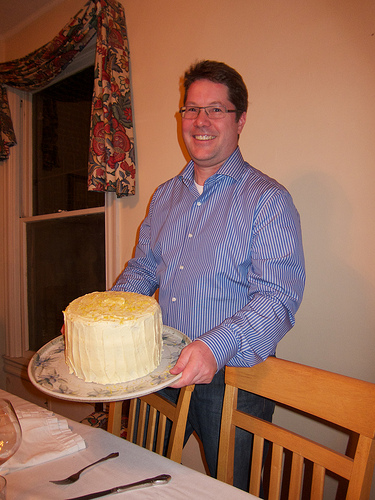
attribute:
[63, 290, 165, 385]
cake — frosted, tall, homemade, cream colored, round, multi-layer, for celebration, yellow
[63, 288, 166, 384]
frosting — white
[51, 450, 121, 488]
fork — silver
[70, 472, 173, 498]
butter knife — silver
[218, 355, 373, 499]
chair back — wooden, stained, light, solid wood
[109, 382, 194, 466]
chair back — wooden, solid wood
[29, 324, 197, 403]
platter — china, large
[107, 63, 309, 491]
man — smiling, happy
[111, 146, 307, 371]
shirt — blue, dress shirt, striped, white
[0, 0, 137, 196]
curtain — flowered, patterned, busy, floral, red, beige, green, paisley, hanging, white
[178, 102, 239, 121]
glasses — dark-rimmed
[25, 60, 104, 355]
window — large, dark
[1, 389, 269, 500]
table cloth — white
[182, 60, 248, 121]
hair — brown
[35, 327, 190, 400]
design — floral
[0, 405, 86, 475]
napkin — folded, stacked, linen, white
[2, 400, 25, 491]
glass — wine glass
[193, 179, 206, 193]
t shirt — white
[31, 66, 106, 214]
pane — bare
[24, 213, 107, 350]
pane — bare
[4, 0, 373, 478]
wall — white